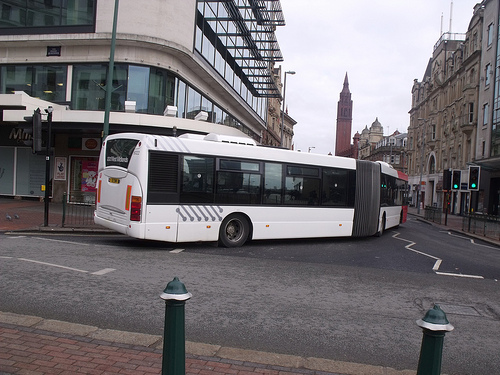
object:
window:
[101, 137, 139, 169]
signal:
[452, 165, 482, 191]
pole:
[468, 192, 474, 232]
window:
[456, 98, 478, 125]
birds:
[3, 212, 14, 220]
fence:
[400, 190, 470, 220]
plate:
[102, 165, 128, 179]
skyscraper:
[334, 70, 354, 152]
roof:
[352, 115, 386, 141]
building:
[336, 73, 408, 175]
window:
[84, 60, 184, 114]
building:
[1, 0, 301, 220]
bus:
[93, 132, 412, 249]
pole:
[106, 1, 120, 129]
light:
[468, 183, 477, 190]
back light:
[130, 195, 142, 221]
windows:
[146, 150, 357, 210]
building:
[405, 0, 500, 226]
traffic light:
[28, 101, 56, 228]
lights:
[454, 184, 459, 189]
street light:
[280, 72, 298, 151]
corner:
[77, 114, 484, 264]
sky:
[286, 1, 431, 98]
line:
[393, 226, 484, 284]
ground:
[260, 242, 445, 300]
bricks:
[6, 314, 422, 375]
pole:
[160, 277, 196, 373]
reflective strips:
[158, 290, 193, 302]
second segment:
[93, 131, 360, 249]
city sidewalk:
[4, 317, 398, 374]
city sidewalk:
[4, 187, 104, 232]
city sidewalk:
[413, 210, 499, 249]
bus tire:
[219, 214, 251, 248]